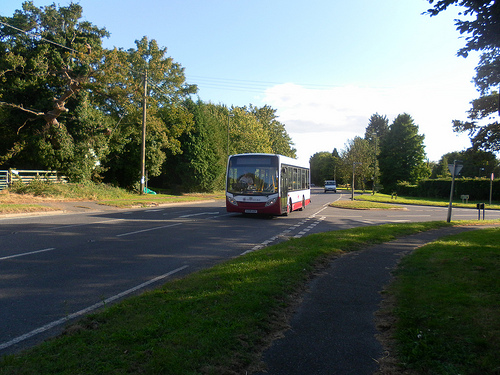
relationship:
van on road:
[323, 180, 337, 193] [7, 194, 334, 356]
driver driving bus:
[262, 168, 277, 189] [227, 152, 313, 214]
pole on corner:
[442, 154, 461, 219] [313, 209, 484, 235]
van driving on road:
[322, 178, 337, 191] [2, 185, 339, 346]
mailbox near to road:
[464, 152, 498, 228] [332, 205, 479, 216]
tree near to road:
[125, 41, 185, 184] [1, 163, 351, 354]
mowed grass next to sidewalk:
[371, 245, 407, 373] [255, 219, 499, 374]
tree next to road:
[380, 114, 427, 198] [0, 192, 499, 342]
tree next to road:
[364, 117, 385, 183] [0, 192, 499, 342]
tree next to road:
[341, 136, 371, 186] [0, 192, 499, 342]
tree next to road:
[430, 1, 499, 156] [0, 192, 499, 342]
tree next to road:
[329, 149, 340, 179] [0, 192, 499, 342]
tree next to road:
[362, 108, 420, 164] [86, 221, 194, 263]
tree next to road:
[41, 33, 93, 128] [86, 221, 194, 263]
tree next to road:
[203, 92, 237, 126] [86, 221, 194, 263]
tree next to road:
[125, 41, 185, 184] [0, 178, 242, 335]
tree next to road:
[125, 41, 185, 184] [48, 196, 301, 275]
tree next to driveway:
[3, 1, 150, 189] [0, 193, 339, 347]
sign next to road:
[464, 178, 498, 214] [336, 209, 483, 217]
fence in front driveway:
[1, 170, 68, 188] [39, 197, 124, 214]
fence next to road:
[11, 148, 63, 185] [1, 200, 310, 317]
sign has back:
[439, 149, 461, 232] [442, 150, 467, 179]